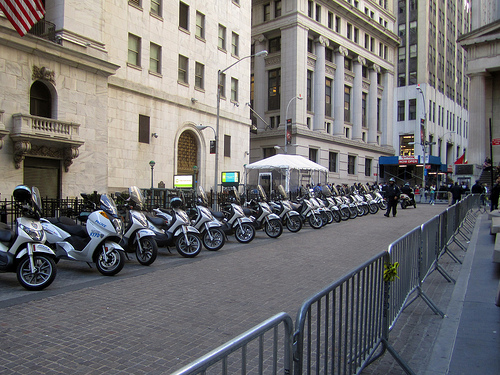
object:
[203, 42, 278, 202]
light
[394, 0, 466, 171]
building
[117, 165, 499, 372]
barriers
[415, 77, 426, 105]
light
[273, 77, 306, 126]
light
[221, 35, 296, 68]
light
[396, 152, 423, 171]
sign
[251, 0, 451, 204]
building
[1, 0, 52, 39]
flag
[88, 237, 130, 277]
tire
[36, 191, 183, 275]
motorcycle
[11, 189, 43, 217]
handlebars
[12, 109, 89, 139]
balcony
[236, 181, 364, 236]
mopeds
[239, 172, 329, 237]
mopeds whole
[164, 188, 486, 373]
fence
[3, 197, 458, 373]
walkway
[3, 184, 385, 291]
mopeds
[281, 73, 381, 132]
windows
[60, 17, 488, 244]
building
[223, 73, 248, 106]
window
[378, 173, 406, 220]
person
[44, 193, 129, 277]
motorbike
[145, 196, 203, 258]
motorbike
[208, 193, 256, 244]
motorbike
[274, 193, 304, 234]
motorbike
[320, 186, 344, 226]
motorbike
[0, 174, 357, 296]
motorcycles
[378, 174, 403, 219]
police man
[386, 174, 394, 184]
helmet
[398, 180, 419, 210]
person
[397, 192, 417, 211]
moped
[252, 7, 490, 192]
building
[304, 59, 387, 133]
pillars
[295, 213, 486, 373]
barrier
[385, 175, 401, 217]
man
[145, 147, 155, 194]
lamppost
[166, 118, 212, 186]
doors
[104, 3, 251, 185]
building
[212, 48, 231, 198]
pole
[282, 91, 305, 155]
pole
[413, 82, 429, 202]
pole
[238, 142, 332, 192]
tent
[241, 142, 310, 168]
white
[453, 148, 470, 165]
flag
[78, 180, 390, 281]
motorbikes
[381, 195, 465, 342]
fence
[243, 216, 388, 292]
bricks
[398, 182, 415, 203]
motorcycle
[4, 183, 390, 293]
row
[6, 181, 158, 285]
motorbikes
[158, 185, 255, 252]
motorbikes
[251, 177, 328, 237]
motorbikes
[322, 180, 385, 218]
motorbikes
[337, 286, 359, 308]
metal barricade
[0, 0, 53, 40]
american flag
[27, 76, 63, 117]
window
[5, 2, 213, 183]
building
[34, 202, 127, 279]
motorcycle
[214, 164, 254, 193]
billboard